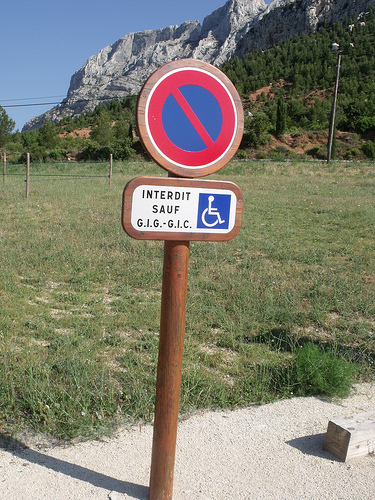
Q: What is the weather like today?
A: It is clear.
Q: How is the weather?
A: It is clear.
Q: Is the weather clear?
A: Yes, it is clear.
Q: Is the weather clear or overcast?
A: It is clear.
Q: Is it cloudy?
A: No, it is clear.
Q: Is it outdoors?
A: Yes, it is outdoors.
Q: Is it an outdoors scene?
A: Yes, it is outdoors.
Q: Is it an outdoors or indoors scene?
A: It is outdoors.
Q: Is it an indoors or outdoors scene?
A: It is outdoors.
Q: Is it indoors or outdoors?
A: It is outdoors.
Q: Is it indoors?
A: No, it is outdoors.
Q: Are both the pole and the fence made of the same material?
A: Yes, both the pole and the fence are made of wood.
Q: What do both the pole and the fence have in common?
A: The material, both the pole and the fence are wooden.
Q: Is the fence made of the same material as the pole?
A: Yes, both the fence and the pole are made of wood.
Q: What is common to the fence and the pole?
A: The material, both the fence and the pole are wooden.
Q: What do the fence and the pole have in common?
A: The material, both the fence and the pole are wooden.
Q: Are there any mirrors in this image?
A: No, there are no mirrors.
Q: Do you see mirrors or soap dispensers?
A: No, there are no mirrors or soap dispensers.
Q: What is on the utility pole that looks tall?
A: The power lines are on the telephone pole.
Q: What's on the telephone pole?
A: The power lines are on the telephone pole.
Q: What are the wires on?
A: The wires are on the telephone pole.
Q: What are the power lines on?
A: The wires are on the telephone pole.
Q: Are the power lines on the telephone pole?
A: Yes, the power lines are on the telephone pole.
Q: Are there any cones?
A: No, there are no cones.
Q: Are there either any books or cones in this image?
A: No, there are no cones or books.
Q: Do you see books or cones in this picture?
A: No, there are no cones or books.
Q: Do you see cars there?
A: No, there are no cars.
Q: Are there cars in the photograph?
A: No, there are no cars.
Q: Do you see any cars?
A: No, there are no cars.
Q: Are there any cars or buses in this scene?
A: No, there are no cars or buses.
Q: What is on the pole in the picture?
A: The sign is on the pole.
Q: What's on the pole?
A: The sign is on the pole.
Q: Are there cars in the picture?
A: No, there are no cars.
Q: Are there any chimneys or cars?
A: No, there are no cars or chimneys.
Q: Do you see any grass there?
A: Yes, there is grass.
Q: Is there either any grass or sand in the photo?
A: Yes, there is grass.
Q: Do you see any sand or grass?
A: Yes, there is grass.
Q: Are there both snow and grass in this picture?
A: No, there is grass but no snow.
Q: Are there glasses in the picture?
A: No, there are no glasses.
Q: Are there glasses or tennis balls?
A: No, there are no glasses or tennis balls.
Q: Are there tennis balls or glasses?
A: No, there are no glasses or tennis balls.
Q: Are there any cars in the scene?
A: No, there are no cars.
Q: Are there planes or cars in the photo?
A: No, there are no cars or planes.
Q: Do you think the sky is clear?
A: Yes, the sky is clear.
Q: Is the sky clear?
A: Yes, the sky is clear.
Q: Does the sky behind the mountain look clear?
A: Yes, the sky is clear.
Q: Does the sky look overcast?
A: No, the sky is clear.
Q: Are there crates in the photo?
A: No, there are no crates.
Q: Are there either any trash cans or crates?
A: No, there are no crates or trash cans.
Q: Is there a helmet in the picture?
A: No, there are no helmets.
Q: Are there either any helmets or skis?
A: No, there are no helmets or skis.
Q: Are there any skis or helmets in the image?
A: No, there are no helmets or skis.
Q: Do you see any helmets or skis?
A: No, there are no helmets or skis.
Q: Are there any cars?
A: No, there are no cars.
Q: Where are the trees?
A: The trees are on the mountain.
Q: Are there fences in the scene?
A: Yes, there is a fence.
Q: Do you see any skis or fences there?
A: Yes, there is a fence.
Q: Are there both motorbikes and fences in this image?
A: No, there is a fence but no motorcycles.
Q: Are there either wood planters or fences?
A: Yes, there is a wood fence.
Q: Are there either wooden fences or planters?
A: Yes, there is a wood fence.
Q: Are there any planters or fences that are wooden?
A: Yes, the fence is wooden.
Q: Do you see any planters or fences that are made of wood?
A: Yes, the fence is made of wood.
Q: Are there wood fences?
A: Yes, there is a fence that is made of wood.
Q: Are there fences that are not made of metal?
A: Yes, there is a fence that is made of wood.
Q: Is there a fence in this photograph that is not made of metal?
A: Yes, there is a fence that is made of wood.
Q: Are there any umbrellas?
A: No, there are no umbrellas.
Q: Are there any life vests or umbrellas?
A: No, there are no umbrellas or life vests.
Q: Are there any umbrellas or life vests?
A: No, there are no umbrellas or life vests.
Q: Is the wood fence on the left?
A: Yes, the fence is on the left of the image.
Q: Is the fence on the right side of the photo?
A: No, the fence is on the left of the image.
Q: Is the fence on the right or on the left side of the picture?
A: The fence is on the left of the image.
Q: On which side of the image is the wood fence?
A: The fence is on the left of the image.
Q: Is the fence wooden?
A: Yes, the fence is wooden.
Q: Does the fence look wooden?
A: Yes, the fence is wooden.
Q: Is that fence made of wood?
A: Yes, the fence is made of wood.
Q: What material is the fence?
A: The fence is made of wood.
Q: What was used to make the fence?
A: The fence is made of wood.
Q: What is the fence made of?
A: The fence is made of wood.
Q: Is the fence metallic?
A: No, the fence is wooden.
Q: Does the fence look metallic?
A: No, the fence is wooden.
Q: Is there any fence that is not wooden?
A: No, there is a fence but it is wooden.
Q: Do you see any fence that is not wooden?
A: No, there is a fence but it is wooden.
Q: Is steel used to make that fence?
A: No, the fence is made of wood.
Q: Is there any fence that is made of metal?
A: No, there is a fence but it is made of wood.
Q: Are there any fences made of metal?
A: No, there is a fence but it is made of wood.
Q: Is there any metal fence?
A: No, there is a fence but it is made of wood.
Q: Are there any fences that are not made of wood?
A: No, there is a fence but it is made of wood.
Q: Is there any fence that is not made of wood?
A: No, there is a fence but it is made of wood.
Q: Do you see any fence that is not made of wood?
A: No, there is a fence but it is made of wood.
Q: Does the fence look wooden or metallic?
A: The fence is wooden.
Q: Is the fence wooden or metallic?
A: The fence is wooden.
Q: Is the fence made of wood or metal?
A: The fence is made of wood.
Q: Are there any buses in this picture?
A: No, there are no buses.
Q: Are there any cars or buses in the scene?
A: No, there are no buses or cars.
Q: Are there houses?
A: No, there are no houses.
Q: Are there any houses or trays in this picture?
A: No, there are no houses or trays.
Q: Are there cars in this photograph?
A: No, there are no cars.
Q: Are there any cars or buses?
A: No, there are no cars or buses.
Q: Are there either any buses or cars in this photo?
A: No, there are no cars or buses.